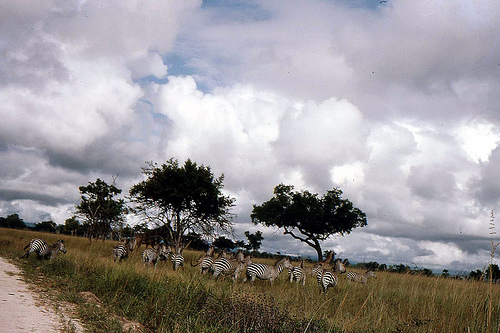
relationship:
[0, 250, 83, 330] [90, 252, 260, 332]
dirt road near field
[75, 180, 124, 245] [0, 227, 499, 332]
green trees in grassy field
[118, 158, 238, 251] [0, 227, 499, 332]
green trees in grassy field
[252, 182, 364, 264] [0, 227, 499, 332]
green trees in grassy field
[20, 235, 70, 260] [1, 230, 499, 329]
zebra walking through field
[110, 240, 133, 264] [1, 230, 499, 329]
zebra walking through field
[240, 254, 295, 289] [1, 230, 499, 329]
zebra walking through field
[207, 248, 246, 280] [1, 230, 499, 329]
zebra walking through field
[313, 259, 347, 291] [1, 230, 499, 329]
zebra walking through field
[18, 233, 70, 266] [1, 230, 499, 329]
zebra running into field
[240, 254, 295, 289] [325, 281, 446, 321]
zebra standing in grass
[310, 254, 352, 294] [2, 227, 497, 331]
zebra standing in grass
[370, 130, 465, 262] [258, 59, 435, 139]
clouds in sky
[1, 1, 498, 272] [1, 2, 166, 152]
sky poking throught clouds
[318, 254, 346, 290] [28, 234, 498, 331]
zebra standing on grass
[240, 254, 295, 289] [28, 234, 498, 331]
zebra standing on grass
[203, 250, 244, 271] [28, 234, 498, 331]
zebra standing on grass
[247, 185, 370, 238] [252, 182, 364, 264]
branch of green trees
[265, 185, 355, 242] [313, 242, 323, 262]
branch sticking out of tree trunk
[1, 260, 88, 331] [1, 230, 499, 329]
dirt alongside field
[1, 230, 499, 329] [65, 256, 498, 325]
field of grass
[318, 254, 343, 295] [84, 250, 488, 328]
zebra in tall grass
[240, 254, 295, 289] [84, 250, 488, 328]
zebra in tall grass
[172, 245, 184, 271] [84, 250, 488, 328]
zebra in tall grass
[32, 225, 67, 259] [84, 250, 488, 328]
zebra in tall grass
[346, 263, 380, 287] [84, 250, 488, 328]
zebra in tall grass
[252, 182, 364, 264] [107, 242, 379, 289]
green trees near zebras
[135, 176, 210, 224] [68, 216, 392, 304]
tree near zebras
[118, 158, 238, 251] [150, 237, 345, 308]
green trees near zebras